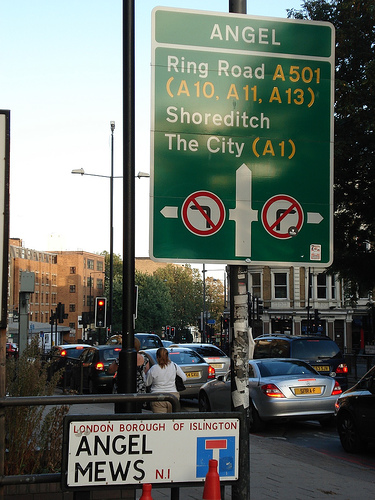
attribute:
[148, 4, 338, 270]
sign — Shoreditch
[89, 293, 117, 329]
traffic light — red, lit up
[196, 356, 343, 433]
car — many, silver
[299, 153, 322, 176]
ground —  white 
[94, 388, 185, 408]
railing — black, metal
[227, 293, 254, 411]
tape —  gray 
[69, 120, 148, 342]
lamp — tall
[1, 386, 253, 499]
fence — Metal 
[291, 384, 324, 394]
license plate — yellow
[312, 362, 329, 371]
license plate — yellow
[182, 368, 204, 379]
license plate — yellow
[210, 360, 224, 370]
license plate — yellow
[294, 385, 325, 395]
license plate — yellow 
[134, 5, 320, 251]
sign — green, white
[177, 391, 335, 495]
street — busy 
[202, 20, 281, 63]
word — angel